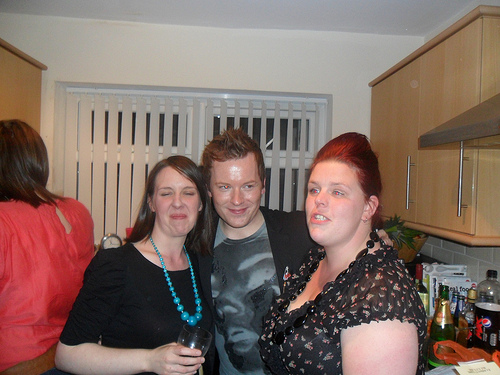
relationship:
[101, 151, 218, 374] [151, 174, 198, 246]
woman has face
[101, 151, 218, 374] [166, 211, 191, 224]
woman has mouth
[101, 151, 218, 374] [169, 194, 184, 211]
woman has nose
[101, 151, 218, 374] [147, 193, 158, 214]
woman has ear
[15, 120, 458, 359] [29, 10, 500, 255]
people together in kitchen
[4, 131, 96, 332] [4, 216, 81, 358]
woman wearing shirt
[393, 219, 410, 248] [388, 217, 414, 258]
leaf on plant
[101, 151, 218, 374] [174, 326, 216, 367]
woman holding glass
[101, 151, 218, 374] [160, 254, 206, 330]
woman wearing necklace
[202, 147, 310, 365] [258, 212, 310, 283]
man wearing coat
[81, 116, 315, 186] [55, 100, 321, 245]
blinds covering window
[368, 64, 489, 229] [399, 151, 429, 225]
cabinets have handle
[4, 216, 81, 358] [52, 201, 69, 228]
shirt has hole